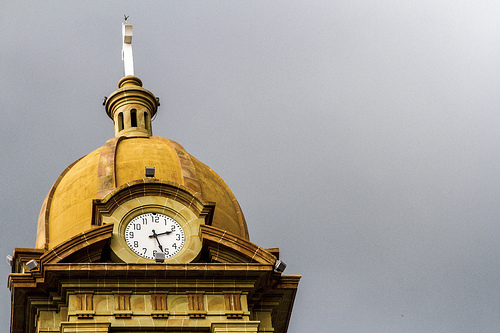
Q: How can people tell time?
A: Clock on tower.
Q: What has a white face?
A: Clock.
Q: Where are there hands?
A: Clock Face.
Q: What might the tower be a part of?
A: Church.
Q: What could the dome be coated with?
A: Gold.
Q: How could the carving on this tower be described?
A: Ornate.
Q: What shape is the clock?
A: Round.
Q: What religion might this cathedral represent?
A: Catholic.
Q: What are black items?
A: Numbers.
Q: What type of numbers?
A: Latin.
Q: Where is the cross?
A: On cupola.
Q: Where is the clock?
A: On tower.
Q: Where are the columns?
A: On building.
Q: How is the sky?
A: Gray.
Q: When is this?
A: Daytime.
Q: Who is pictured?
A: No one.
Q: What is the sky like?
A: Overcast.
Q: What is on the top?
A: Cross.